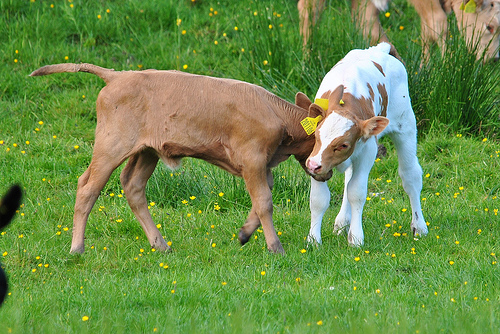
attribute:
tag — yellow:
[301, 112, 314, 132]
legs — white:
[306, 147, 429, 247]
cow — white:
[304, 35, 434, 261]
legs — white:
[300, 135, 435, 244]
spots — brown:
[364, 61, 391, 124]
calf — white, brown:
[305, 40, 431, 250]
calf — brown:
[27, 61, 332, 256]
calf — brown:
[29, 60, 386, 254]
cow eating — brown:
[230, 94, 407, 207]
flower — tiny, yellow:
[351, 256, 360, 264]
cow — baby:
[289, 37, 459, 281]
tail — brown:
[30, 51, 110, 97]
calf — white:
[32, 51, 347, 268]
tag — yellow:
[294, 110, 319, 137]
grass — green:
[350, 263, 458, 332]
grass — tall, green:
[173, 23, 274, 75]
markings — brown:
[373, 90, 393, 122]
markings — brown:
[309, 58, 387, 128]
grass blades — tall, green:
[417, 24, 497, 123]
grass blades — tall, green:
[229, 14, 356, 74]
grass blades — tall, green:
[157, 166, 242, 216]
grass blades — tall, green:
[267, 167, 308, 207]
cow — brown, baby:
[23, 57, 325, 271]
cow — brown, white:
[294, 29, 437, 252]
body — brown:
[77, 74, 274, 212]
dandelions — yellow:
[353, 250, 363, 265]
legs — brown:
[231, 170, 293, 260]